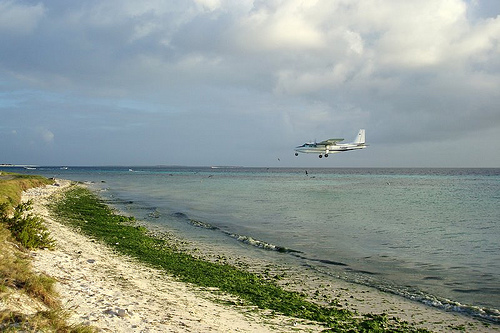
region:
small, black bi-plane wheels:
[292, 151, 330, 159]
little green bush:
[1, 196, 58, 252]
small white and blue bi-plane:
[290, 125, 365, 156]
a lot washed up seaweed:
[50, 180, 415, 330]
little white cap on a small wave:
[230, 228, 277, 251]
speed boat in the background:
[24, 165, 39, 170]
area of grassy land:
[0, 170, 57, 331]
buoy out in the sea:
[303, 167, 308, 177]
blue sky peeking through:
[0, 89, 183, 116]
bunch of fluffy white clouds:
[227, 0, 499, 103]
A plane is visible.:
[278, 100, 419, 230]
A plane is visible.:
[302, 131, 367, 233]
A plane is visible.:
[294, 114, 465, 292]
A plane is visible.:
[274, 91, 366, 168]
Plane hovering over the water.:
[280, 130, 392, 157]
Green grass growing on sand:
[69, 175, 288, 330]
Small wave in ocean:
[173, 180, 348, 266]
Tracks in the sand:
[74, 241, 195, 312]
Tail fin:
[355, 111, 372, 151]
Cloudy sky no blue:
[68, 15, 273, 105]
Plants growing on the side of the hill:
[13, 181, 48, 250]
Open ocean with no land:
[5, 154, 158, 184]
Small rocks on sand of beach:
[196, 240, 379, 318]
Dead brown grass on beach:
[9, 266, 56, 303]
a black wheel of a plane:
[292, 151, 300, 158]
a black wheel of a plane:
[318, 151, 324, 160]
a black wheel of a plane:
[325, 151, 330, 158]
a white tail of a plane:
[352, 129, 370, 144]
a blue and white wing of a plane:
[316, 134, 339, 146]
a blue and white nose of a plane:
[295, 143, 304, 150]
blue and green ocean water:
[5, 164, 498, 320]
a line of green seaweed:
[50, 173, 394, 330]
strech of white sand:
[15, 170, 305, 332]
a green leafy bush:
[12, 199, 56, 252]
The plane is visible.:
[275, 110, 407, 224]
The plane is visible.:
[247, 97, 337, 191]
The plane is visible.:
[288, 91, 453, 296]